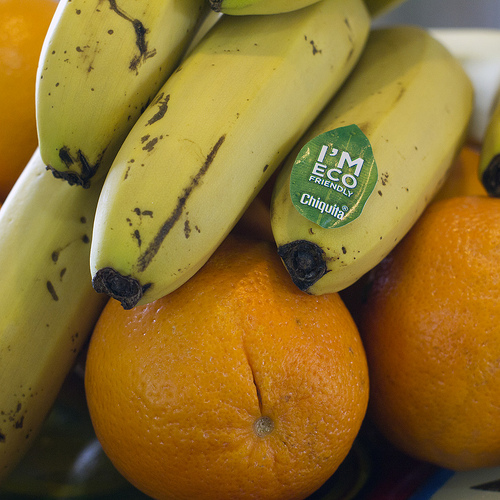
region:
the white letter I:
[309, 138, 336, 170]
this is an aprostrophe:
[323, 143, 340, 162]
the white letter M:
[333, 141, 367, 178]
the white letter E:
[309, 159, 329, 179]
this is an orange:
[51, 235, 393, 497]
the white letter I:
[346, 187, 355, 200]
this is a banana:
[243, 16, 483, 291]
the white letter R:
[314, 174, 324, 186]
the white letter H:
[305, 193, 317, 208]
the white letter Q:
[311, 198, 329, 216]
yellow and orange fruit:
[4, 0, 499, 490]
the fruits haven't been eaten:
[1, 3, 496, 496]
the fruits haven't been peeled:
[1, 0, 498, 497]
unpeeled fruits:
[2, 0, 499, 480]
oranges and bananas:
[0, 0, 499, 499]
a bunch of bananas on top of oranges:
[4, 1, 494, 495]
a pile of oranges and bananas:
[5, 1, 495, 496]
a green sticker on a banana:
[280, 108, 425, 282]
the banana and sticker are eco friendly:
[262, 0, 468, 296]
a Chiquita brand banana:
[201, 2, 492, 306]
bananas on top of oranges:
[4, 2, 496, 494]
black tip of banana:
[88, 246, 167, 311]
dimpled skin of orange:
[86, 269, 369, 498]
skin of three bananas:
[42, 3, 478, 305]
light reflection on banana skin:
[87, 163, 130, 270]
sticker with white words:
[292, 123, 378, 227]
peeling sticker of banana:
[291, 122, 378, 228]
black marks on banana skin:
[104, 134, 233, 271]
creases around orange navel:
[210, 376, 301, 468]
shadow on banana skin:
[199, 4, 318, 63]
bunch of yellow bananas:
[0, 0, 475, 482]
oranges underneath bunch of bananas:
[82, 138, 498, 498]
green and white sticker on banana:
[288, 122, 380, 230]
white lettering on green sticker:
[299, 143, 365, 219]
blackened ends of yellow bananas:
[92, 239, 327, 311]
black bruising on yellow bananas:
[40, 0, 227, 271]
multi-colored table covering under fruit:
[1, 336, 498, 498]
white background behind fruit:
[424, 29, 499, 140]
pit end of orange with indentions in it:
[220, 341, 294, 466]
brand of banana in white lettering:
[298, 192, 348, 221]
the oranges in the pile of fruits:
[83, 148, 498, 498]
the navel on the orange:
[255, 416, 272, 435]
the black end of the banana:
[278, 240, 328, 290]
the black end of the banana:
[92, 269, 142, 313]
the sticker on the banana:
[288, 123, 377, 228]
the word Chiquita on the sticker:
[299, 192, 342, 220]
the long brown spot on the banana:
[136, 133, 226, 273]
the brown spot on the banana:
[45, 278, 60, 303]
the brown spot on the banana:
[303, 33, 323, 56]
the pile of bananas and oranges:
[1, 0, 499, 498]